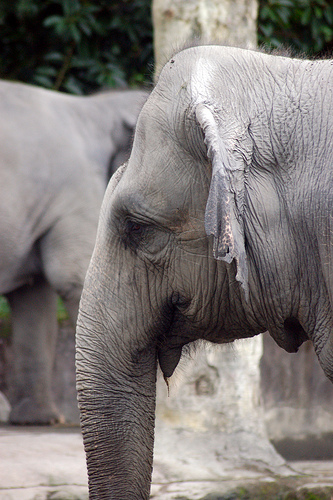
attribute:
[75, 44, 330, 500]
elephant — gray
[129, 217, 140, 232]
eye — open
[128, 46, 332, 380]
skin — wrinkled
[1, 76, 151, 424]
elephant — gray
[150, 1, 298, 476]
tree — white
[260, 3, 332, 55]
leaves — green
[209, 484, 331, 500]
weeds — green